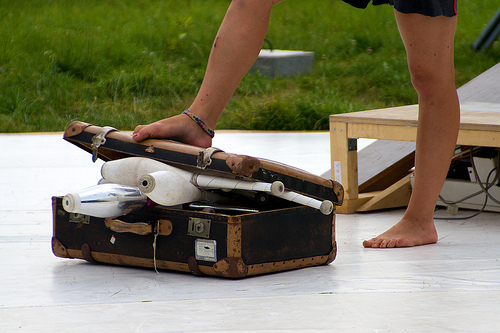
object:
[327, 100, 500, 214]
wooden bench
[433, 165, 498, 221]
cords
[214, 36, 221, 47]
cut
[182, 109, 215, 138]
band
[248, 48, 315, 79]
metal box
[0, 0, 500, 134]
grass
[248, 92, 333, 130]
tall grass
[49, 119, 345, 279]
box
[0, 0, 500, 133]
ground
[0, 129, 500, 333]
ground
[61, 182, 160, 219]
equipment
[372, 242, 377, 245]
toenail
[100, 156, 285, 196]
bowling pin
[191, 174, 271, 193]
neck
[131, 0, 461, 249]
person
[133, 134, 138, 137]
nail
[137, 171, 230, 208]
juggling pins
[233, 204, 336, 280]
side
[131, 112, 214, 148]
foot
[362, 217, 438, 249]
foot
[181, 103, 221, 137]
ankle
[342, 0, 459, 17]
shorts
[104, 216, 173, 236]
handle